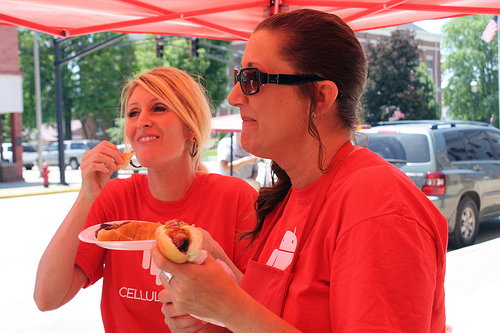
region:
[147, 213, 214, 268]
hot dog on hot dog bun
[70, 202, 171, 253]
hot dog on white paper plate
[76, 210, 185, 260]
white paper plate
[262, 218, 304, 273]
white image on front of red t-shirt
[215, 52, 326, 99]
black sun glasses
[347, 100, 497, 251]
grey suv parked next to sidewalk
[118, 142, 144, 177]
one hoop ear ring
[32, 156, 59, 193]
red fire hydrant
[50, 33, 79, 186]
metal traffic light support pole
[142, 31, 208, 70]
two traffic lights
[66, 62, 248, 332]
A woman with blonde hair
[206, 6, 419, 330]
A woman with brown hair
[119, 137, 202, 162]
Black hooped earrings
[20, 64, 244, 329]
A woman holding up a chip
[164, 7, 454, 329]
A woman holding up a hotdog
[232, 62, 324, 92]
A pair of black sunglasses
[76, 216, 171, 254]
A round white disposable plate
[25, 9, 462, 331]
Two women wearing red shirts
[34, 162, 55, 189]
A red fire hydrant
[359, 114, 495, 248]
A grey SUV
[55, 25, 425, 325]
Two women eating hot dogs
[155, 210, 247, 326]
Woman holding a hot dog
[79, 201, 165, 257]
Hotdog in a paper plate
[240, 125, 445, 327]
Woman wearing a red shirt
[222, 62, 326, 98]
Woman wearing black sunglasses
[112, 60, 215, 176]
Woman with blonde hair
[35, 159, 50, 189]
Red fire hydrant across the street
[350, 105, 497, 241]
SUV parked along the curb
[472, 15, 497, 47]
American flag on a flag pole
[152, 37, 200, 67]
Two traffic light signals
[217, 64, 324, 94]
Sunglasses on womans face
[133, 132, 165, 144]
Woman smiling showing teeth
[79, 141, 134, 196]
Hand holding onto a chip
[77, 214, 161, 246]
Hot dog on a plate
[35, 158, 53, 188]
Fire hydrant in the distance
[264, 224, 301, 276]
Character on womans shirt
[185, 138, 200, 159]
Right hooped earing on womans ear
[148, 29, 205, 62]
Two traffic lights in the distance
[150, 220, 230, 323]
Womans hand holding a hotdog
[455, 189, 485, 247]
Back wheel of a car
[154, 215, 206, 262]
a hot dog on top of woman's hand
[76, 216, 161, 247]
a white plate containing a hot dog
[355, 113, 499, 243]
a parked minivan on the side of a street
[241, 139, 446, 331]
woman wearing a red shirt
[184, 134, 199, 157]
woman wearing a round loop for a earring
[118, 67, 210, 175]
woman with blonde hair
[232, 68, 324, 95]
woman wearing thick black sunglasses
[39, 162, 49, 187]
a red fire hydrant on the corner of a street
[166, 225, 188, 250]
a wiener in a hot dog bun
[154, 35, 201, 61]
a set of streetlights